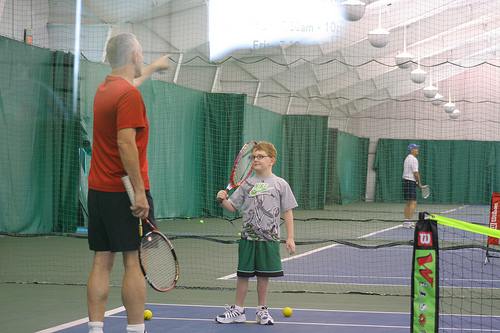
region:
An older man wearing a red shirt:
[68, 29, 171, 329]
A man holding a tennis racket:
[82, 30, 190, 331]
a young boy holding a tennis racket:
[199, 122, 310, 329]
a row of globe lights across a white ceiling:
[321, 2, 465, 127]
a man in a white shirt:
[375, 132, 434, 235]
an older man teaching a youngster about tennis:
[65, 25, 320, 330]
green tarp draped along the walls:
[3, 26, 499, 228]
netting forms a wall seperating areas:
[3, 3, 499, 330]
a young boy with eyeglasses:
[189, 129, 316, 326]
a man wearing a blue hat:
[397, 142, 425, 170]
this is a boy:
[204, 133, 307, 323]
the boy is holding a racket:
[214, 137, 254, 196]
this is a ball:
[279, 303, 297, 318]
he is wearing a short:
[241, 247, 282, 272]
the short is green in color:
[234, 237, 279, 269]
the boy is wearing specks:
[248, 150, 266, 162]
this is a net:
[327, 115, 414, 256]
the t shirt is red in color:
[96, 80, 121, 135]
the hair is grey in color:
[106, 34, 132, 64]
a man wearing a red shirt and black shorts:
[88, 31, 178, 331]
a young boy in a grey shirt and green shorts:
[216, 139, 296, 323]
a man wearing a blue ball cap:
[400, 140, 430, 228]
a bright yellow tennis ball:
[281, 306, 294, 316]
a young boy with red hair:
[214, 141, 296, 325]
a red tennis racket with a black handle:
[214, 136, 261, 208]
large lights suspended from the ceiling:
[342, 3, 463, 120]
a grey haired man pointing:
[80, 32, 171, 331]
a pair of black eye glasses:
[249, 152, 270, 159]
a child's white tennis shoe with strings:
[217, 303, 249, 323]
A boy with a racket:
[207, 113, 287, 323]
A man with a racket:
[81, 36, 202, 307]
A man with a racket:
[394, 124, 445, 206]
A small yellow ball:
[278, 299, 306, 331]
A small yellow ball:
[135, 294, 167, 322]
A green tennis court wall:
[7, 40, 69, 231]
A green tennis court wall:
[151, 72, 242, 214]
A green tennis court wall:
[281, 112, 341, 222]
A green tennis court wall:
[332, 129, 370, 193]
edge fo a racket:
[136, 244, 153, 306]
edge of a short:
[258, 271, 268, 283]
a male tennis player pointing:
[85, 30, 180, 332]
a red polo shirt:
[90, 74, 150, 191]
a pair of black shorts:
[86, 187, 158, 252]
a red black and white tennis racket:
[119, 175, 180, 293]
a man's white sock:
[88, 321, 105, 332]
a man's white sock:
[123, 322, 143, 332]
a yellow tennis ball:
[143, 306, 153, 319]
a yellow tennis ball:
[283, 306, 293, 315]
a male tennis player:
[399, 142, 429, 225]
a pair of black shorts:
[401, 177, 416, 199]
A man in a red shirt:
[72, 83, 151, 313]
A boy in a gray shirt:
[213, 90, 284, 269]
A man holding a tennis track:
[63, 170, 210, 297]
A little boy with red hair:
[205, 126, 295, 195]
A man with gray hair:
[108, 28, 145, 95]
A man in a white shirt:
[347, 143, 437, 239]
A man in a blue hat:
[396, 132, 427, 161]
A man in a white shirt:
[360, 150, 425, 230]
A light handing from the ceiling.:
[370, 29, 393, 52]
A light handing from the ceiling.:
[343, 4, 363, 18]